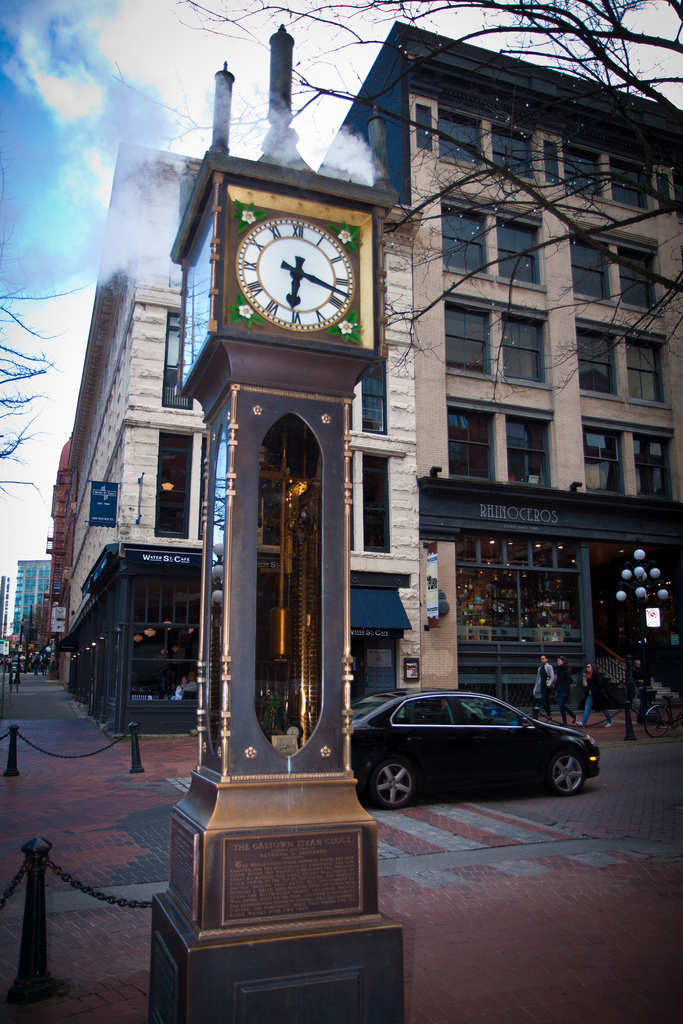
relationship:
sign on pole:
[644, 606, 661, 628] [642, 630, 663, 706]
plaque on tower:
[172, 808, 200, 927] [142, 151, 410, 1022]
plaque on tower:
[219, 820, 368, 927] [142, 151, 410, 1022]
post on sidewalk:
[8, 830, 59, 993] [7, 869, 639, 1019]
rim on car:
[374, 760, 413, 807] [353, 693, 601, 804]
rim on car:
[552, 753, 586, 793] [353, 693, 601, 804]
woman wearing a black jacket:
[571, 663, 618, 729] [586, 669, 610, 713]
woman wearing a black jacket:
[549, 653, 577, 726] [550, 652, 577, 725]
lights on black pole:
[614, 544, 672, 603] [618, 606, 640, 742]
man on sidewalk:
[530, 640, 558, 723] [10, 661, 680, 761]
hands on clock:
[274, 253, 334, 312] [222, 182, 369, 342]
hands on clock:
[284, 254, 311, 316] [222, 182, 369, 342]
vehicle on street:
[349, 678, 606, 812] [1, 721, 674, 999]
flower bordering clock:
[241, 205, 250, 223] [231, 208, 354, 332]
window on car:
[462, 690, 506, 724] [353, 693, 601, 804]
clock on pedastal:
[223, 211, 351, 331] [203, 378, 409, 1021]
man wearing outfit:
[530, 640, 558, 724] [526, 663, 558, 724]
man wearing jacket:
[530, 640, 558, 724] [528, 658, 564, 687]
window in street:
[388, 693, 460, 728] [3, 735, 680, 900]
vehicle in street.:
[349, 677, 606, 811] [527, 779, 679, 853]